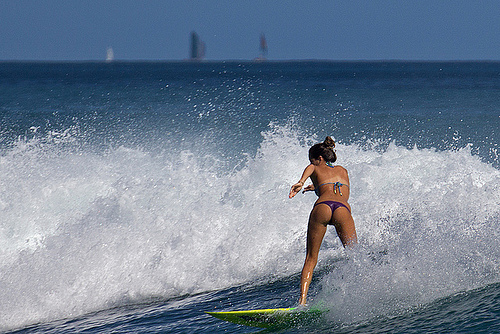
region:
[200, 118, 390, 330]
a woman surfing in the ocean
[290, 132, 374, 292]
a woman in a bikini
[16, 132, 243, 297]
a large wave crashing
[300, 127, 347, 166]
a woman's hair in a bun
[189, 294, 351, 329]
a yellow and green surfboard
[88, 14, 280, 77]
three sail boats in the background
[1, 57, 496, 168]
a blue and blue-green ocean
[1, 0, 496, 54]
a clear blue sky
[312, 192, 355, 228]
a purple bikini bottom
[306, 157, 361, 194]
a blue string bikini top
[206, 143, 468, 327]
Surfer in the ocean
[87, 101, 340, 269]
White water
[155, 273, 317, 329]
Yellow surfboard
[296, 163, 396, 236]
Woman in a bikini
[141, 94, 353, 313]
Surfing in the ocean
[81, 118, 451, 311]
Riding the waves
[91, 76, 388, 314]
Nice day in the ocean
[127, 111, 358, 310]
A surfer catching a large wave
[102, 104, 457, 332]
Lots of white water from the wave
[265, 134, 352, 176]
Woman with hair up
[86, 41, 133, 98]
white object in the far ground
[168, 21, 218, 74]
tall black boat with large sail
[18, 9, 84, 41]
gray skies overhead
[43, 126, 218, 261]
large wave in the water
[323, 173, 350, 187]
tan on woman's back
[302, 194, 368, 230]
wedgie in woman's butt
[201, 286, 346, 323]
green surf board in water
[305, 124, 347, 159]
woman's hair in pony tail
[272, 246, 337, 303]
water on woman's foot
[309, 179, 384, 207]
woman's blue bikini top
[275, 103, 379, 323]
Surfer riding wave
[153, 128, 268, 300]
White water in the waves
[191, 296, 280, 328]
Surfboard in the water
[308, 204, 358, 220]
Surfer's swimsuit bottom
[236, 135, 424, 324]
Woman surfing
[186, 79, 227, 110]
The ocean with nice waves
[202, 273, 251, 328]
Yellow surfboard on the waves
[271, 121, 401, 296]
Girl surfing in the ocean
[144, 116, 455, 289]
The waves on the ocean water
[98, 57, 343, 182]
Blue ocean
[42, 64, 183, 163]
This water is very blue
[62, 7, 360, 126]
these boats are in water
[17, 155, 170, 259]
Waves can get very high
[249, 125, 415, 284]
this girl is wearing a bikini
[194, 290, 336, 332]
this surf board is yellow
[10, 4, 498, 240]
today looks like a nice day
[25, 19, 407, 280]
the water looks mean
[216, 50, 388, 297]
this girl is tan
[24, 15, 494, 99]
the boats are far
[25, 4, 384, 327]
the sky is also blue